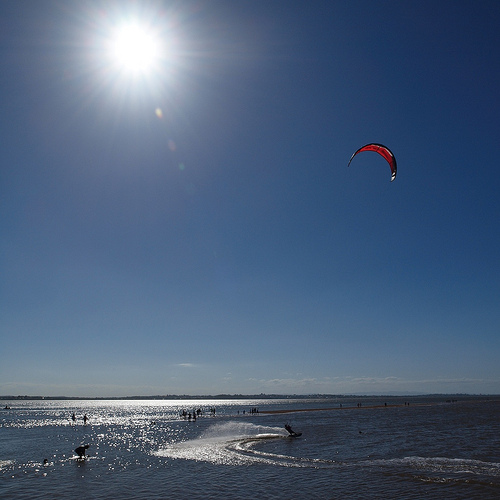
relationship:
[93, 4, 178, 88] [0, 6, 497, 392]
sun in sky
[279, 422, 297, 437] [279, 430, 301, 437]
man on h surfboard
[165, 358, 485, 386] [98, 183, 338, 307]
clouds in sky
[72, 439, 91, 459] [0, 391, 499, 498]
person in water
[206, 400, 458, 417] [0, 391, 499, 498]
sand barge in water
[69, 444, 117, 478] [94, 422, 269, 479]
person in water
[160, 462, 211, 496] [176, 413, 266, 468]
waves in water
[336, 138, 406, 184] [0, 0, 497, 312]
kite in sky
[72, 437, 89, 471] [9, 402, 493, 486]
person leaning over water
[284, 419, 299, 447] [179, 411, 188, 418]
person leaning over person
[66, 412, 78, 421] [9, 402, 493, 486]
person leaning over water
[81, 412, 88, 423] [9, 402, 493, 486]
person leaning over water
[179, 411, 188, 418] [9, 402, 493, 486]
person leaning over water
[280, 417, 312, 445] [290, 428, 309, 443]
person riding board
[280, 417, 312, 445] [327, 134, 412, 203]
person holding kite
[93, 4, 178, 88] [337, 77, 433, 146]
sun in sky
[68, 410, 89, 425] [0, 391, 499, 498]
people standing in water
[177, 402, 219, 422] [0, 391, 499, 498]
people standing in water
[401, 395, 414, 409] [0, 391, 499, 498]
people standing in water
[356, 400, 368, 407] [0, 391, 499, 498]
people standing in water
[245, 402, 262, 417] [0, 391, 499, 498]
people standing in water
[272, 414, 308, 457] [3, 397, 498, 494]
people parasailing in water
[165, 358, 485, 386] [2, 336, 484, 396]
clouds on horizon